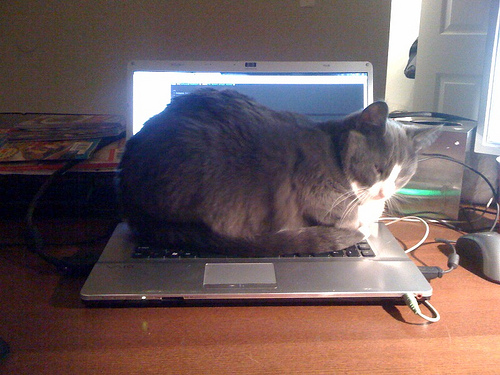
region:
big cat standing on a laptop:
[118, 89, 442, 252]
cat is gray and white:
[119, 92, 442, 250]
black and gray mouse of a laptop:
[451, 229, 498, 282]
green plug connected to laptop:
[406, 297, 424, 317]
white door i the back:
[408, 3, 498, 130]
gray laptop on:
[83, 62, 433, 309]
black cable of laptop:
[26, 120, 124, 275]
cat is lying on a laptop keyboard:
[117, 87, 446, 259]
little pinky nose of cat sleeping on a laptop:
[368, 190, 384, 202]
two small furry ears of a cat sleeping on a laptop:
[357, 100, 442, 150]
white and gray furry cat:
[117, 88, 443, 256]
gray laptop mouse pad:
[201, 261, 276, 284]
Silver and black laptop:
[81, 58, 433, 309]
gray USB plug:
[417, 265, 441, 277]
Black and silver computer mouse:
[453, 230, 498, 284]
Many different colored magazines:
[1, 112, 126, 175]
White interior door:
[412, 1, 499, 137]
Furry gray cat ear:
[357, 99, 389, 137]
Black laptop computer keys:
[134, 238, 372, 256]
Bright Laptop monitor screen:
[126, 59, 373, 136]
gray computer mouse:
[456, 231, 498, 281]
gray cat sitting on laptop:
[104, 84, 426, 254]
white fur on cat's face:
[373, 183, 395, 198]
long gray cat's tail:
[140, 213, 357, 254]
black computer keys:
[132, 241, 165, 261]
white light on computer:
[137, 293, 149, 299]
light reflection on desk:
[138, 320, 153, 332]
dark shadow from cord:
[383, 302, 398, 319]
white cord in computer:
[404, 294, 424, 323]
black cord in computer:
[43, 244, 94, 282]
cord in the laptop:
[400, 295, 442, 330]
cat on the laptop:
[110, 89, 414, 254]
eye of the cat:
[356, 150, 383, 179]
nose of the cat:
[375, 186, 395, 203]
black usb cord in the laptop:
[417, 255, 463, 287]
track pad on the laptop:
[196, 255, 282, 288]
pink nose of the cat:
[370, 190, 396, 201]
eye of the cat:
[397, 171, 414, 186]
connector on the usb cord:
[445, 254, 458, 270]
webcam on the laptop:
[237, 55, 261, 67]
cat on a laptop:
[117, 78, 430, 287]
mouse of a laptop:
[195, 256, 280, 298]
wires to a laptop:
[394, 208, 460, 326]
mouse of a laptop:
[453, 224, 495, 288]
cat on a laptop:
[76, 46, 441, 332]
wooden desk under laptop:
[126, 319, 411, 374]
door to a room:
[403, 0, 494, 142]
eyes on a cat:
[369, 154, 414, 188]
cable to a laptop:
[28, 174, 107, 273]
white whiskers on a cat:
[329, 185, 368, 220]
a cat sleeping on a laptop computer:
[77, 61, 444, 306]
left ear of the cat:
[355, 94, 392, 145]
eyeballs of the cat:
[369, 158, 411, 188]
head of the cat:
[335, 95, 425, 201]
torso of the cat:
[185, 90, 316, 230]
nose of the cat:
[375, 185, 390, 197]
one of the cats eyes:
[367, 160, 382, 175]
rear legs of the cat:
[143, 138, 264, 238]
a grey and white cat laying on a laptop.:
[78, 64, 446, 301]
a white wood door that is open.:
[389, 0, 498, 141]